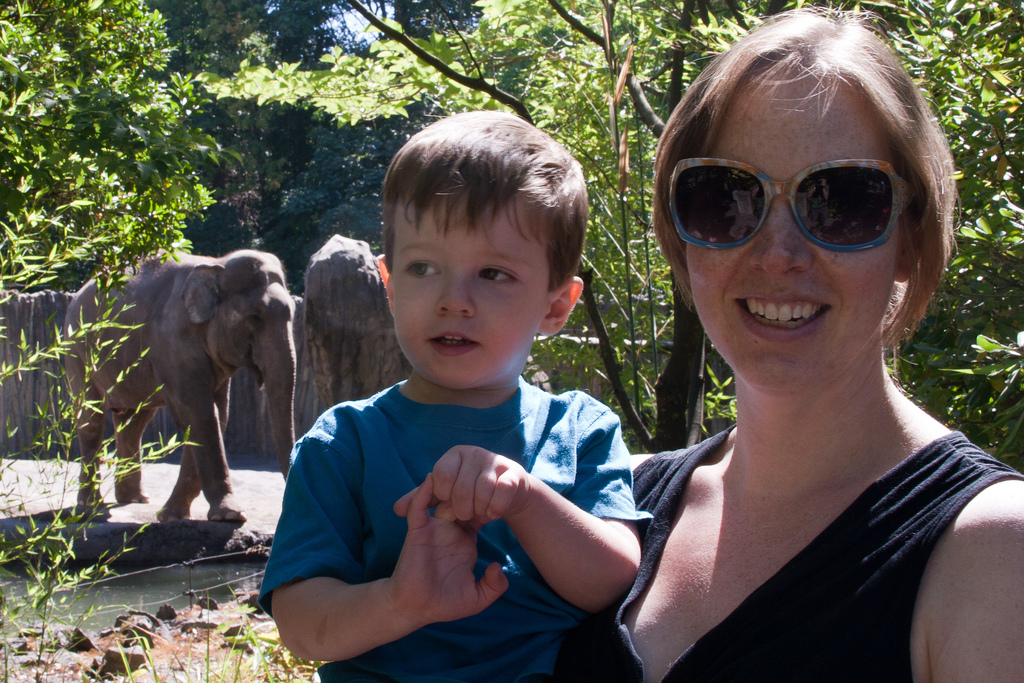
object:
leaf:
[184, 441, 203, 446]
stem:
[72, 378, 247, 522]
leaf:
[211, 623, 228, 634]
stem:
[206, 591, 209, 679]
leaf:
[235, 594, 244, 607]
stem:
[239, 594, 241, 680]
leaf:
[68, 535, 76, 560]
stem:
[0, 534, 80, 599]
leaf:
[61, 535, 67, 546]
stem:
[0, 512, 77, 557]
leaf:
[27, 566, 40, 578]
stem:
[0, 571, 43, 614]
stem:
[19, 506, 35, 619]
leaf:
[28, 512, 34, 530]